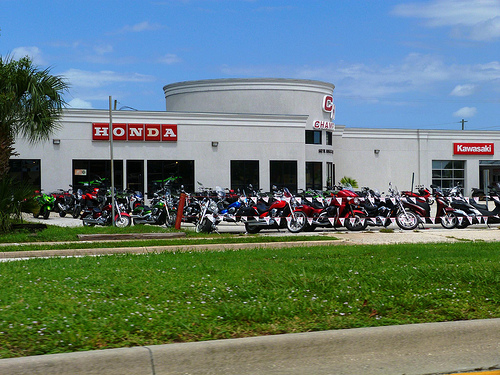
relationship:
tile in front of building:
[161, 124, 177, 140] [0, 79, 499, 220]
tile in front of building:
[145, 124, 159, 141] [0, 79, 499, 220]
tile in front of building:
[128, 124, 145, 139] [0, 79, 499, 220]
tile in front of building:
[111, 121, 128, 141] [0, 79, 499, 220]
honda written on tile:
[92, 122, 178, 142] [161, 124, 177, 140]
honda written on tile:
[92, 122, 178, 142] [145, 124, 159, 141]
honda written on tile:
[92, 122, 178, 142] [111, 121, 128, 141]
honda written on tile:
[92, 122, 178, 142] [128, 124, 145, 139]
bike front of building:
[109, 188, 175, 227] [0, 79, 499, 220]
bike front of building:
[248, 191, 315, 233] [0, 79, 499, 220]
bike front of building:
[301, 191, 367, 229] [0, 79, 499, 220]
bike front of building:
[354, 187, 421, 231] [0, 79, 499, 220]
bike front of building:
[391, 182, 458, 230] [0, 79, 499, 220]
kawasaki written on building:
[452, 140, 494, 155] [0, 79, 499, 220]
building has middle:
[0, 79, 499, 220] [162, 77, 335, 120]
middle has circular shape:
[162, 77, 335, 120] [164, 75, 338, 118]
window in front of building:
[74, 158, 127, 193] [0, 79, 499, 220]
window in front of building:
[149, 158, 195, 197] [0, 79, 499, 220]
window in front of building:
[228, 159, 263, 193] [0, 79, 499, 220]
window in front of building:
[269, 159, 297, 188] [0, 79, 499, 220]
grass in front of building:
[0, 238, 495, 355] [0, 79, 499, 220]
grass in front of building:
[0, 223, 331, 250] [0, 79, 499, 220]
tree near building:
[0, 55, 68, 232] [0, 79, 499, 220]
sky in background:
[0, 0, 498, 129] [3, 1, 498, 131]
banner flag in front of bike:
[237, 194, 248, 205] [248, 191, 315, 233]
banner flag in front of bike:
[250, 196, 258, 203] [248, 191, 315, 233]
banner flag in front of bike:
[238, 216, 250, 226] [248, 191, 315, 233]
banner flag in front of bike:
[264, 216, 272, 228] [248, 191, 315, 233]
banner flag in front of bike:
[203, 213, 218, 224] [248, 191, 315, 233]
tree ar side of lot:
[0, 55, 68, 232] [6, 182, 496, 232]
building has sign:
[0, 79, 499, 220] [90, 123, 178, 142]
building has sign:
[0, 79, 499, 220] [448, 142, 495, 157]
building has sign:
[0, 79, 499, 220] [319, 91, 336, 112]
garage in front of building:
[479, 163, 499, 199] [0, 79, 499, 220]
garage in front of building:
[3, 159, 43, 205] [0, 79, 499, 220]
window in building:
[74, 158, 127, 193] [0, 79, 499, 220]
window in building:
[149, 158, 195, 197] [0, 79, 499, 220]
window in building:
[228, 159, 263, 193] [0, 79, 499, 220]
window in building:
[269, 159, 297, 188] [0, 79, 499, 220]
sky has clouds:
[0, 0, 498, 129] [0, 1, 497, 119]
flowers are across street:
[0, 264, 396, 344] [0, 228, 498, 374]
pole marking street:
[172, 190, 185, 231] [0, 228, 498, 374]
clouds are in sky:
[0, 1, 497, 119] [0, 0, 498, 129]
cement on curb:
[0, 317, 497, 374] [4, 319, 496, 374]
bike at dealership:
[391, 182, 458, 230] [3, 76, 495, 215]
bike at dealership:
[354, 187, 421, 231] [3, 76, 495, 215]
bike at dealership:
[248, 191, 315, 233] [3, 76, 495, 215]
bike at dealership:
[196, 194, 263, 235] [3, 76, 495, 215]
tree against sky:
[0, 55, 68, 232] [0, 0, 498, 129]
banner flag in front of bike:
[237, 194, 248, 205] [196, 194, 263, 235]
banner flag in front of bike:
[203, 213, 218, 224] [196, 194, 263, 235]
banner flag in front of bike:
[238, 216, 250, 226] [196, 194, 263, 235]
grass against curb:
[0, 238, 495, 355] [4, 319, 496, 374]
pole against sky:
[457, 117, 468, 130] [0, 0, 498, 129]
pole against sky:
[113, 100, 119, 108] [0, 0, 498, 129]